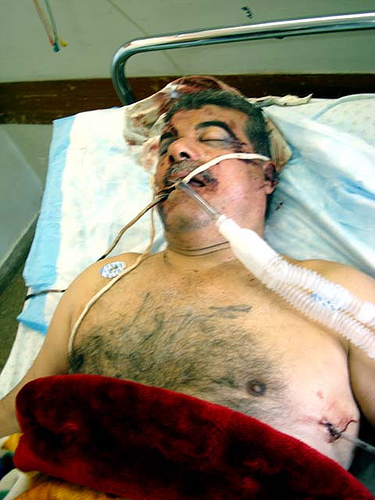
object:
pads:
[100, 259, 126, 278]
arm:
[0, 252, 138, 436]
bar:
[97, 11, 373, 86]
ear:
[263, 160, 279, 196]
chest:
[123, 255, 324, 401]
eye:
[159, 141, 173, 154]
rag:
[117, 86, 227, 136]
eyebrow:
[195, 121, 235, 137]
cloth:
[39, 106, 125, 261]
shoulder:
[73, 251, 152, 340]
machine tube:
[174, 174, 217, 225]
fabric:
[6, 371, 373, 499]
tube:
[163, 176, 222, 218]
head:
[151, 89, 277, 256]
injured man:
[5, 87, 374, 500]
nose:
[167, 137, 200, 164]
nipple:
[248, 377, 268, 396]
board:
[0, 72, 371, 127]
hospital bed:
[1, 11, 372, 485]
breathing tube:
[168, 174, 373, 358]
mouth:
[162, 173, 206, 193]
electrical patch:
[101, 260, 124, 279]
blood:
[262, 157, 279, 205]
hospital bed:
[18, 111, 365, 496]